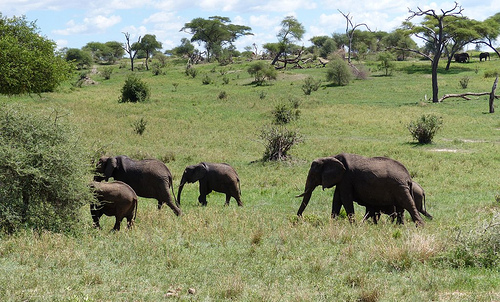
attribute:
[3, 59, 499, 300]
grass — dry, large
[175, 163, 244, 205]
baby elephant — grey, small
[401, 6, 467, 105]
tree — tall, bare, leafless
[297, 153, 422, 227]
elephant — grey, walking, large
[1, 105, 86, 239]
bush — light green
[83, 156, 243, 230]
elephants — grey, walking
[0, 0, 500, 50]
sky — cloudy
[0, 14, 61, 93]
bush — dark green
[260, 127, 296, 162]
bush — brown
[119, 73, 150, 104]
bush — small, green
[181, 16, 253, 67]
tree — green